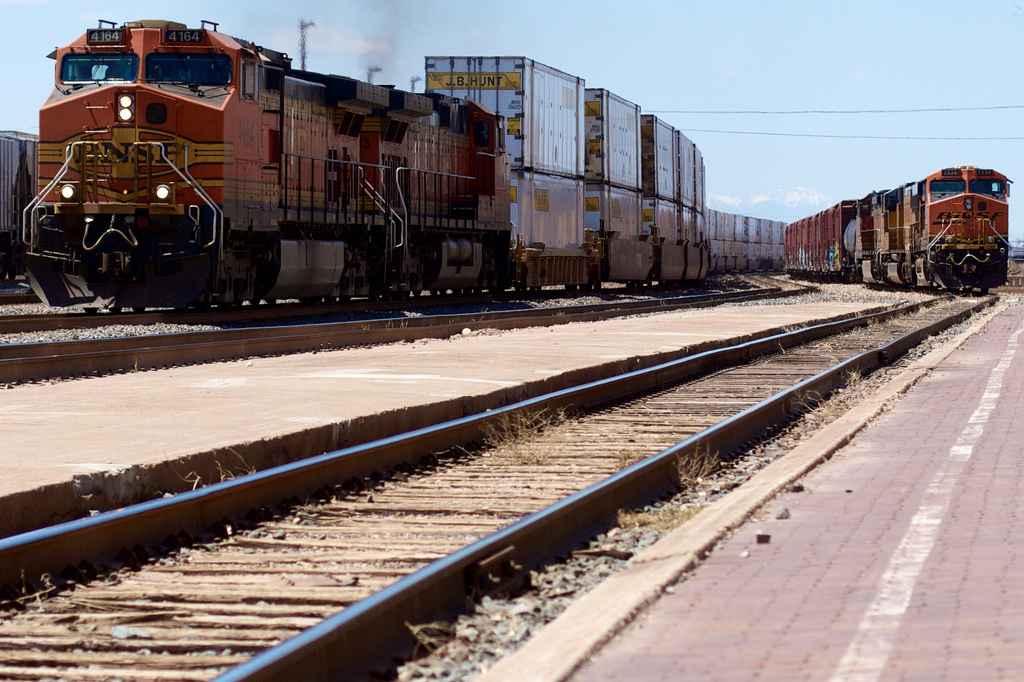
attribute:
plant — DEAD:
[835, 361, 873, 393]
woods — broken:
[38, 583, 238, 666]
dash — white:
[892, 326, 1001, 680]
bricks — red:
[983, 405, 1019, 503]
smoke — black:
[349, 0, 406, 80]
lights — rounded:
[153, 175, 177, 199]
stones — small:
[748, 474, 813, 558]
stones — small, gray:
[386, 539, 617, 679]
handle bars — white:
[359, 168, 407, 251]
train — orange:
[31, 25, 787, 311]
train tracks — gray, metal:
[0, 295, 1004, 668]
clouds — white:
[685, 42, 758, 80]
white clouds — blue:
[660, 58, 756, 84]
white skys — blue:
[841, 52, 936, 90]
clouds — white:
[619, 25, 794, 64]